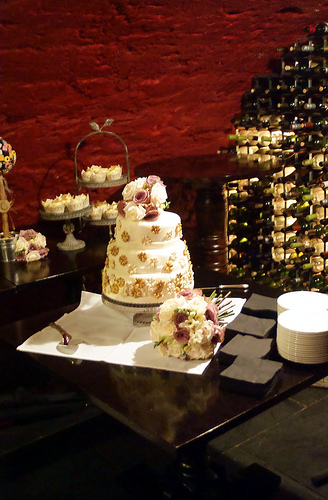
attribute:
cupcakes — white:
[32, 142, 147, 258]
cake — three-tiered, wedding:
[91, 180, 197, 319]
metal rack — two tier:
[78, 118, 142, 230]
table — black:
[18, 235, 293, 426]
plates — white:
[275, 305, 327, 364]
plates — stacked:
[274, 285, 326, 367]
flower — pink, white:
[132, 187, 150, 204]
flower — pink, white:
[149, 182, 168, 203]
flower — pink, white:
[116, 199, 126, 217]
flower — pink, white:
[122, 200, 146, 222]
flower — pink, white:
[142, 204, 159, 221]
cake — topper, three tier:
[99, 175, 194, 307]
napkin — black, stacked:
[220, 354, 286, 386]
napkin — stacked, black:
[219, 333, 272, 356]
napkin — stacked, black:
[226, 311, 278, 336]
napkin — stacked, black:
[242, 293, 279, 311]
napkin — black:
[242, 289, 278, 316]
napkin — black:
[225, 307, 276, 336]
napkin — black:
[219, 354, 286, 391]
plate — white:
[277, 310, 326, 334]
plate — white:
[276, 290, 327, 309]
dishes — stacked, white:
[276, 308, 327, 365]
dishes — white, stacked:
[274, 291, 327, 314]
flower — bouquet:
[142, 207, 162, 220]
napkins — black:
[219, 292, 284, 398]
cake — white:
[81, 146, 239, 335]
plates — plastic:
[272, 305, 327, 368]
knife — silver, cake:
[189, 280, 249, 293]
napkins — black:
[228, 299, 257, 321]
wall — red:
[1, 1, 327, 239]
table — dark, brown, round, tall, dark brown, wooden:
[135, 147, 287, 273]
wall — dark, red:
[2, 0, 327, 268]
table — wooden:
[1, 274, 321, 482]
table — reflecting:
[0, 222, 105, 325]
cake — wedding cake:
[83, 171, 196, 295]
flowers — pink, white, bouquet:
[149, 288, 237, 363]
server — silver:
[42, 308, 112, 381]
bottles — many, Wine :
[215, 21, 326, 292]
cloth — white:
[91, 304, 170, 366]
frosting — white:
[125, 248, 133, 257]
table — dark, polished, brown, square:
[4, 259, 327, 492]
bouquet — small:
[118, 173, 171, 218]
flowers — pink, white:
[112, 171, 178, 218]